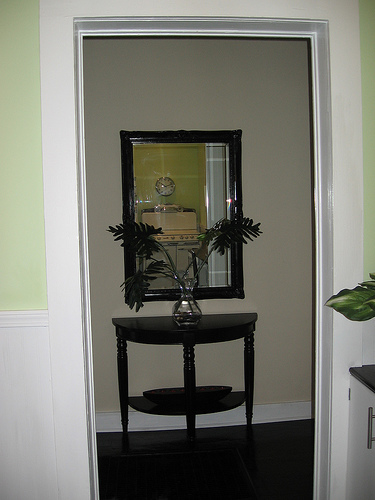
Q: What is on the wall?
A: Mirror.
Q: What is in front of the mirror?
A: Plant.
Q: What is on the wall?
A: Brown mirror.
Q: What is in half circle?
A: Two shelves.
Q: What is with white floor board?
A: Pale yellow wall.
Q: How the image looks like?
A: Good.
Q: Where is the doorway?
A: Center of wall.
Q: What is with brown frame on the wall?
A: Mirror.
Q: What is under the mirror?
A: Table.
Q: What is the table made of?
A: Wood.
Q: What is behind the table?
A: White baseboard on the wall.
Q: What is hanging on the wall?
A: A mirror.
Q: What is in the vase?
A: Leaves.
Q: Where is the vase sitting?
A: On the table.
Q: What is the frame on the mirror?
A: Black.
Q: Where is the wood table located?
A: Under the mirror.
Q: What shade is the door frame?
A: White.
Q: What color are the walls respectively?
A: Green, white, and beige.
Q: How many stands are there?
A: 1.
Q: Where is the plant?
A: On the stand.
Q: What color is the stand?
A: Black.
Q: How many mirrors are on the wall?
A: 1.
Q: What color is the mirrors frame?
A: Black.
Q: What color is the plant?
A: Green.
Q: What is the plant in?
A: The vase.